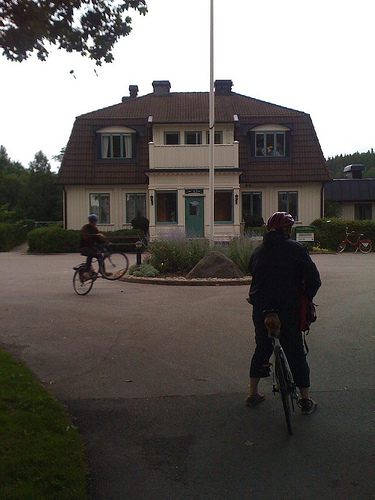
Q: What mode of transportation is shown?
A: Bicycles.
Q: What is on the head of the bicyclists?
A: Helmets.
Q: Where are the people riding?
A: Driveway.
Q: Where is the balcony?
A: Second floor over the door.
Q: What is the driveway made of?
A: Concrete.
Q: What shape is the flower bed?
A: Round.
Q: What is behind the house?
A: Trees.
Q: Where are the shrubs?
A: Around the house.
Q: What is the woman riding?
A: Bike.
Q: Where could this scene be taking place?
A: Driveway.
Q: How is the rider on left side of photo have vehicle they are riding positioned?
A: On one wheel.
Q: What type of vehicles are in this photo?
A: Bicycles.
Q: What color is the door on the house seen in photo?
A: Turquoise.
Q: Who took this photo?
A: Photographer.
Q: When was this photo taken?
A: Daylight.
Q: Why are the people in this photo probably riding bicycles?
A: Entertainment.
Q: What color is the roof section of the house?
A: Brown.